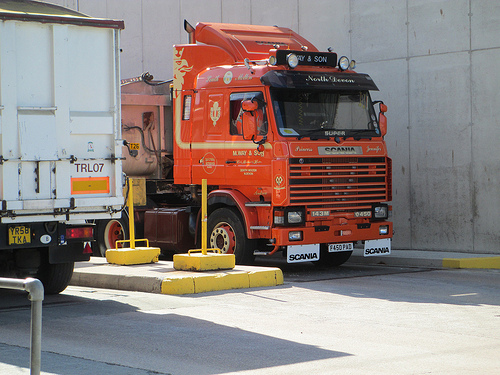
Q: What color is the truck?
A: Orange.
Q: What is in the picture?
A: A truck.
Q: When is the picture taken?
A: Daytime.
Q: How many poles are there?
A: Two.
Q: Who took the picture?
A: Photographer.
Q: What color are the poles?
A: Yellow.